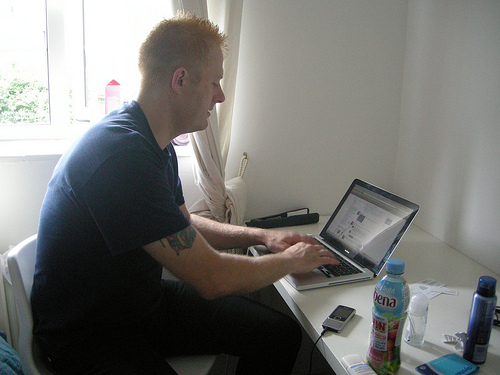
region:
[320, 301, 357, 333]
Cell phone on the table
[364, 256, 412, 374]
Water bottle on the table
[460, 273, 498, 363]
Blue spray on the table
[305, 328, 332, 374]
Black wire of the charger connected to the cell phon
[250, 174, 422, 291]
Laptop on the table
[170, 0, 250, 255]
White curtain next to the man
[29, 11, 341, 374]
Man sitting while using the laptop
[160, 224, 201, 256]
Tattoo on man's arm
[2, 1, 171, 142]
Open window next to the man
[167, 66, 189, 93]
Right ear of the man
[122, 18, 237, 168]
man with red hair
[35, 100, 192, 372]
tattoo shows under the sleeve of navy blue shirt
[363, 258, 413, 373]
a light blue bottle of a beverage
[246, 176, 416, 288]
a laptop is in use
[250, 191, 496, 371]
white Formica table top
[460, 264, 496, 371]
steely blue aerosol can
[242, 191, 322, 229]
a black stapler on it's side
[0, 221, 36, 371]
a back of a white chair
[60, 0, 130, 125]
an open casement window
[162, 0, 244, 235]
twisted white window curtain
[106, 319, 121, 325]
black fabric on shirt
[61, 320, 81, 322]
black fabric on shirt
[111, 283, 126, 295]
black fabric on shirt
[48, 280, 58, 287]
black fabric on shirt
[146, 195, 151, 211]
black fabric on shirt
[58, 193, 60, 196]
black fabric on shirt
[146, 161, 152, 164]
black fabric on shirt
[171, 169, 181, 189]
black fabric on shirt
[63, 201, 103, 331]
black fabric on shirt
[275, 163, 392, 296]
laptop on the table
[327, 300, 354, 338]
cellphone on the table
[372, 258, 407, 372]
bottle on the table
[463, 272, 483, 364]
bottle on the table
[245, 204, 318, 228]
hair straightener on table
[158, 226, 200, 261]
tattoo on the man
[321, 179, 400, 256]
screen on the computer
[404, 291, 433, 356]
bottle on the table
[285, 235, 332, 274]
hand of the man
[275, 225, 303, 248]
hand of the man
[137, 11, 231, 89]
orange hair on a man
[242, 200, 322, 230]
a black hair straightener on a desk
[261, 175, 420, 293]
a silver and black laptop on a desk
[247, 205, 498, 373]
a white desk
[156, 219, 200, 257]
a color tattoo on a man's arm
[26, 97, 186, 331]
a navy shirt on a ma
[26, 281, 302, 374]
black pants on a man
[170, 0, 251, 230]
a curtain tied up by a window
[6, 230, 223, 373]
a white chair under a man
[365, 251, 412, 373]
a colorful plastic drink box on a desk